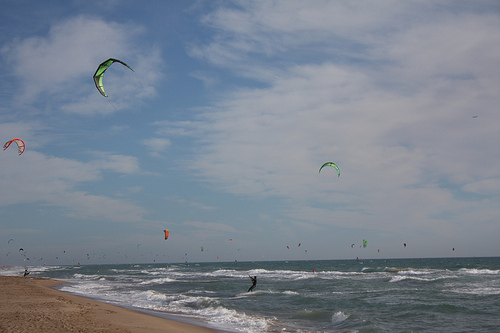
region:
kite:
[81, 43, 135, 110]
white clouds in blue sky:
[248, 59, 352, 113]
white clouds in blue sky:
[357, 179, 384, 199]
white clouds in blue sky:
[301, 146, 379, 201]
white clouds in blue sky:
[345, 8, 420, 48]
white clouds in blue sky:
[137, 186, 208, 226]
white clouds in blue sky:
[270, 131, 335, 186]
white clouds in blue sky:
[80, 191, 157, 231]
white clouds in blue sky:
[205, 85, 276, 146]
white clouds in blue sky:
[227, 108, 307, 156]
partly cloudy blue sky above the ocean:
[0, 0, 497, 262]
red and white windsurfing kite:
[2, 137, 25, 153]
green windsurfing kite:
[91, 58, 133, 98]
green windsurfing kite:
[318, 160, 340, 178]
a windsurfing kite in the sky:
[162, 229, 169, 237]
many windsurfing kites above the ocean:
[0, 228, 457, 276]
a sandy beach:
[1, 274, 236, 331]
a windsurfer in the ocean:
[242, 274, 258, 293]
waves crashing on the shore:
[61, 280, 276, 332]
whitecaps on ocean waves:
[183, 267, 498, 284]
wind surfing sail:
[86, 53, 140, 105]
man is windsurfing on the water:
[246, 272, 258, 292]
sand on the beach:
[3, 276, 204, 331]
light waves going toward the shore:
[67, 264, 363, 330]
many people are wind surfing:
[2, 55, 485, 283]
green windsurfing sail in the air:
[316, 158, 345, 181]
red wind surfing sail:
[161, 225, 173, 241]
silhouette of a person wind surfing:
[246, 272, 257, 291]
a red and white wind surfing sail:
[0, 137, 28, 157]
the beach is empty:
[1, 259, 199, 329]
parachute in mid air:
[88, 53, 141, 100]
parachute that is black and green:
[89, 51, 136, 101]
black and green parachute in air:
[87, 53, 135, 106]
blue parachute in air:
[315, 156, 340, 177]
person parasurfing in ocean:
[86, 55, 261, 292]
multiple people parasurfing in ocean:
[3, 55, 494, 262]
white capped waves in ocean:
[65, 267, 496, 328]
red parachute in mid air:
[157, 226, 177, 243]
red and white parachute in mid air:
[0, 133, 26, 154]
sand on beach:
[2, 270, 206, 332]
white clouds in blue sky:
[272, 26, 322, 71]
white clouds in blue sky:
[349, 43, 417, 88]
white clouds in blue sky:
[338, 155, 385, 205]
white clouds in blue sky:
[232, 182, 283, 223]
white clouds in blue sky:
[305, 99, 355, 158]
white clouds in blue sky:
[102, 212, 129, 234]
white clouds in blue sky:
[157, 159, 205, 211]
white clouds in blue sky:
[219, 64, 241, 100]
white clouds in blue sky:
[267, 158, 303, 205]